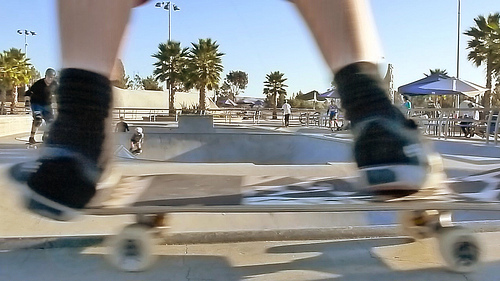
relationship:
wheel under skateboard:
[95, 222, 167, 272] [31, 171, 498, 275]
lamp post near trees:
[151, 0, 183, 137] [151, 26, 225, 126]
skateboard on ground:
[28, 129, 478, 270] [2, 110, 498, 279]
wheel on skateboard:
[102, 225, 164, 272] [65, 201, 498, 273]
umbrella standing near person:
[419, 75, 489, 117] [457, 102, 478, 137]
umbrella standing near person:
[419, 75, 489, 117] [400, 95, 413, 113]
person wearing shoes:
[24, 0, 430, 217] [349, 117, 431, 191]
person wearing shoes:
[24, 0, 430, 217] [17, 145, 96, 222]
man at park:
[280, 100, 291, 126] [0, 0, 500, 280]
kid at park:
[23, 67, 58, 145] [0, 0, 500, 280]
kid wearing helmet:
[127, 125, 145, 152] [133, 122, 145, 132]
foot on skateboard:
[347, 116, 429, 191] [5, 155, 499, 274]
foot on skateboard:
[25, 145, 105, 219] [5, 155, 499, 274]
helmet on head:
[43, 68, 57, 77] [45, 67, 56, 84]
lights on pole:
[12, 25, 38, 35] [21, 33, 30, 59]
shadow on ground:
[1, 230, 497, 279] [2, 110, 498, 279]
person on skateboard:
[24, 0, 430, 217] [5, 155, 499, 274]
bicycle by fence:
[298, 110, 321, 125] [113, 104, 499, 144]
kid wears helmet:
[23, 67, 58, 145] [33, 64, 63, 83]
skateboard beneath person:
[83, 167, 500, 270] [10, 7, 484, 219]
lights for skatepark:
[143, 5, 196, 32] [12, 109, 492, 277]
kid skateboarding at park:
[23, 67, 58, 148] [0, 112, 500, 278]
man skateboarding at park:
[280, 100, 291, 126] [0, 112, 500, 278]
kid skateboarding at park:
[127, 125, 145, 156] [0, 112, 500, 278]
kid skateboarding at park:
[127, 125, 145, 152] [0, 112, 500, 278]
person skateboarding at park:
[6, 0, 444, 224] [0, 112, 500, 278]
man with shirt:
[402, 95, 412, 112] [403, 101, 410, 111]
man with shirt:
[280, 100, 291, 126] [403, 101, 410, 111]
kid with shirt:
[23, 67, 58, 145] [403, 101, 410, 111]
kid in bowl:
[127, 125, 145, 152] [118, 128, 379, 164]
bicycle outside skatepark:
[298, 106, 326, 128] [0, 114, 492, 277]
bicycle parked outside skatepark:
[298, 106, 326, 128] [0, 114, 492, 277]